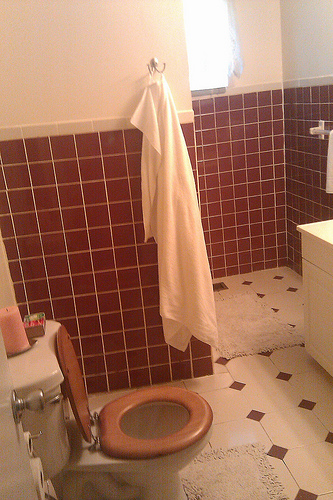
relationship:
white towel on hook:
[146, 72, 217, 354] [144, 52, 169, 70]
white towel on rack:
[136, 76, 218, 354] [143, 52, 167, 74]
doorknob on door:
[12, 387, 45, 423] [0, 332, 39, 497]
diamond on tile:
[244, 406, 266, 422] [217, 367, 261, 403]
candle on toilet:
[0, 305, 29, 353] [3, 320, 212, 499]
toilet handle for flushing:
[45, 372, 77, 423] [45, 388, 169, 423]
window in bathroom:
[187, 3, 247, 119] [13, 179, 331, 487]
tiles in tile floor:
[217, 340, 312, 468] [68, 266, 332, 499]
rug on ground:
[173, 438, 291, 497] [290, 94, 303, 107]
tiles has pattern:
[94, 262, 324, 498] [60, 269, 332, 497]